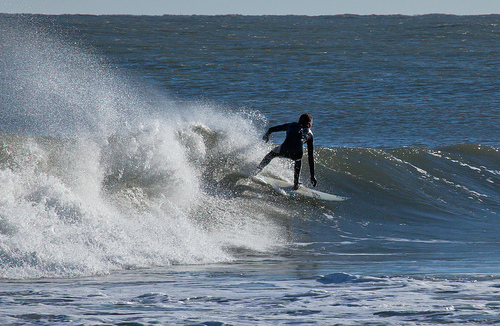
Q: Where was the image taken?
A: It was taken at the ocean.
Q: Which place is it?
A: It is an ocean.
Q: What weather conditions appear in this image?
A: It is clear.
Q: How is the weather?
A: It is clear.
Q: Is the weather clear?
A: Yes, it is clear.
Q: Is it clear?
A: Yes, it is clear.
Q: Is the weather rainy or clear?
A: It is clear.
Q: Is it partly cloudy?
A: No, it is clear.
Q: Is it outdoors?
A: Yes, it is outdoors.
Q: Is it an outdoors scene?
A: Yes, it is outdoors.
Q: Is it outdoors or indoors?
A: It is outdoors.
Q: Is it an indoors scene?
A: No, it is outdoors.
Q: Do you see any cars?
A: No, there are no cars.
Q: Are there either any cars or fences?
A: No, there are no cars or fences.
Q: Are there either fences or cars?
A: No, there are no cars or fences.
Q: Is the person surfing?
A: Yes, the person is surfing.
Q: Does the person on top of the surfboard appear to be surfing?
A: Yes, the person is surfing.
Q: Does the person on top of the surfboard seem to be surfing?
A: Yes, the person is surfing.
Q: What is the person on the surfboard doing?
A: The person is surfing.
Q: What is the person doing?
A: The person is surfing.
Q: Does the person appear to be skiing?
A: No, the person is surfing.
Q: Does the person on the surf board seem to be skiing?
A: No, the person is surfing.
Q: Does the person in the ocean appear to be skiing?
A: No, the person is surfing.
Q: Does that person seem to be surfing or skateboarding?
A: The person is surfing.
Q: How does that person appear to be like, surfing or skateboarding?
A: The person is surfing.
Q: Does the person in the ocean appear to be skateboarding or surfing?
A: The person is surfing.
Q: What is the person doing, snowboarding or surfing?
A: The person is surfing.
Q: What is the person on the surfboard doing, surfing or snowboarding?
A: The person is surfing.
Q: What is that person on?
A: The person is on the surf board.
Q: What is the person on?
A: The person is on the surf board.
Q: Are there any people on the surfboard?
A: Yes, there is a person on the surfboard.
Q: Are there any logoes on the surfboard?
A: No, there is a person on the surfboard.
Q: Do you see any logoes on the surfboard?
A: No, there is a person on the surfboard.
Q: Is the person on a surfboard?
A: Yes, the person is on a surfboard.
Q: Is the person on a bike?
A: No, the person is on a surfboard.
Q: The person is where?
A: The person is in the ocean.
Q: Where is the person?
A: The person is in the ocean.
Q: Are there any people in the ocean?
A: Yes, there is a person in the ocean.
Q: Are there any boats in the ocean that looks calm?
A: No, there is a person in the ocean.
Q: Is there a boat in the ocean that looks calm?
A: No, there is a person in the ocean.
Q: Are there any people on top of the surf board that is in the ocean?
A: Yes, there is a person on top of the surf board.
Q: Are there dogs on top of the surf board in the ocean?
A: No, there is a person on top of the surfboard.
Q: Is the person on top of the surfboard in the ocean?
A: Yes, the person is on top of the surfboard.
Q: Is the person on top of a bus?
A: No, the person is on top of the surfboard.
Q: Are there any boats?
A: No, there are no boats.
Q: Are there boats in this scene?
A: No, there are no boats.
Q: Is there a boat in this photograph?
A: No, there are no boats.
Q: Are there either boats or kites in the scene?
A: No, there are no boats or kites.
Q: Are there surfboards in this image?
A: Yes, there is a surfboard.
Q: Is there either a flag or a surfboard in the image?
A: Yes, there is a surfboard.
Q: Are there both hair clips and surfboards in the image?
A: No, there is a surfboard but no hair clips.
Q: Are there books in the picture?
A: No, there are no books.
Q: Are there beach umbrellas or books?
A: No, there are no books or beach umbrellas.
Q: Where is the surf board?
A: The surf board is in the ocean.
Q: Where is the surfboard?
A: The surf board is in the ocean.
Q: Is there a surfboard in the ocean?
A: Yes, there is a surfboard in the ocean.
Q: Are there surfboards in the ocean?
A: Yes, there is a surfboard in the ocean.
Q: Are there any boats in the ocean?
A: No, there is a surfboard in the ocean.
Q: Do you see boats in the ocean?
A: No, there is a surfboard in the ocean.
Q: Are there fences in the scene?
A: No, there are no fences.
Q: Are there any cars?
A: No, there are no cars.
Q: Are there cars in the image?
A: No, there are no cars.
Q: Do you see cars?
A: No, there are no cars.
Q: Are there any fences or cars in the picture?
A: No, there are no cars or fences.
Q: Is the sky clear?
A: Yes, the sky is clear.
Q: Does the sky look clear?
A: Yes, the sky is clear.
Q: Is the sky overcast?
A: No, the sky is clear.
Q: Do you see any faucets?
A: No, there are no faucets.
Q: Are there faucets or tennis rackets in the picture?
A: No, there are no faucets or tennis rackets.